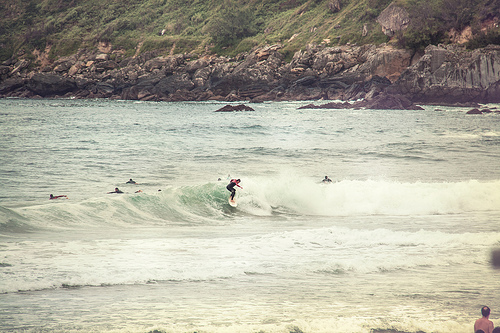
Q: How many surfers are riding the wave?
A: One.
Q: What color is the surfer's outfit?
A: Black.